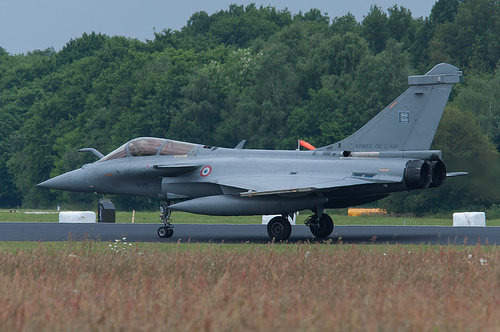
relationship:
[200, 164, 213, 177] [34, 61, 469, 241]
logo on aircraft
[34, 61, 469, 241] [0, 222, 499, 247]
plane on runway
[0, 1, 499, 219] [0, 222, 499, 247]
trees along runway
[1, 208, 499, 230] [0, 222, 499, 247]
grass along runway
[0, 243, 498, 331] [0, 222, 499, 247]
grass along runway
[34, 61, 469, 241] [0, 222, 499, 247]
jet on ground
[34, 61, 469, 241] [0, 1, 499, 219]
jet in front of trees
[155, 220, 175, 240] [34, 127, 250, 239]
small wheel in front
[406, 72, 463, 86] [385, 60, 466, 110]
bar across top of tail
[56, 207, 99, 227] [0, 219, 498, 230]
white blocks along edge of path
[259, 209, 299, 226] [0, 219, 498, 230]
white blocks along edge of path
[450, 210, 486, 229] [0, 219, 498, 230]
white blocks along edge of path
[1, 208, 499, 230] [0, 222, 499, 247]
grass next to runway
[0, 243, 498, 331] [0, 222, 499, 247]
grass next to runway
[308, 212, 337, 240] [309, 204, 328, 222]
wheels on landing gear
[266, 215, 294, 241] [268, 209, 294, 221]
wheels on landing gear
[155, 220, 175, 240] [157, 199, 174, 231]
wheels on landing gear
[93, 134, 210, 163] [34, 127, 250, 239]
windshield in front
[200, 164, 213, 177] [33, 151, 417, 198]
bulls eye on side of jet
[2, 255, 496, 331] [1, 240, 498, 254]
grass next to grass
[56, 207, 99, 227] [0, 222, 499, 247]
white concrete block on side of runway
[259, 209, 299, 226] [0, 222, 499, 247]
white concrete block on side of runway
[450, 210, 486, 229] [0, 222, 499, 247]
white concrete block on side of runway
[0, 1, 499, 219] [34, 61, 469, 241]
trees behind jet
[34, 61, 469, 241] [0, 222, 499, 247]
fighter on runway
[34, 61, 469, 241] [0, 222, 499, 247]
fighter on tarmac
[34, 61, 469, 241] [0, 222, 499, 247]
fighter on ground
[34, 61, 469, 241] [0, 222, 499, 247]
fighter on taxiway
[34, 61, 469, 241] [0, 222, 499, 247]
jet on runway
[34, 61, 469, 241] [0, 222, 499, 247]
jet on tarmac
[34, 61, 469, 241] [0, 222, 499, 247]
jet on taxiway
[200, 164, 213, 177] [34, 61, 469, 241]
target logo on jet